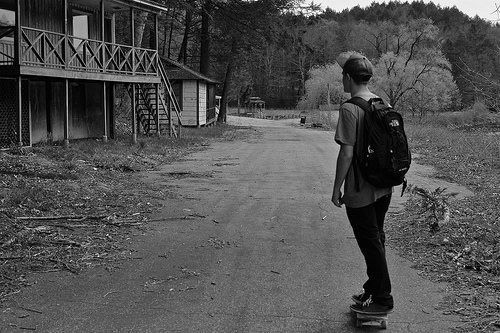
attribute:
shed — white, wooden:
[130, 56, 221, 128]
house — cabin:
[0, 0, 181, 153]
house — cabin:
[143, 51, 220, 128]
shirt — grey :
[335, 92, 395, 209]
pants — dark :
[344, 182, 394, 297]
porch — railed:
[0, 22, 158, 83]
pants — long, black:
[346, 194, 396, 308]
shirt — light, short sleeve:
[333, 91, 392, 207]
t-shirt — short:
[334, 92, 391, 207]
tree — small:
[217, 0, 318, 123]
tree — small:
[226, 66, 256, 116]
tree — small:
[298, 60, 353, 112]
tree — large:
[364, 14, 460, 108]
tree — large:
[283, 13, 343, 98]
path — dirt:
[175, 129, 452, 331]